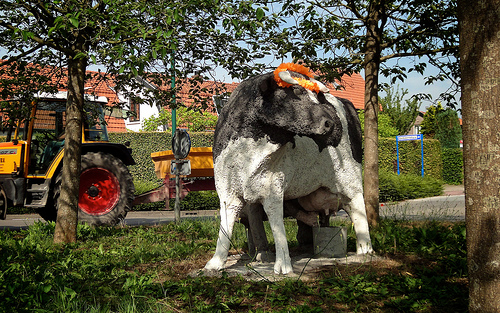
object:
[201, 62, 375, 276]
cow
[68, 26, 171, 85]
tree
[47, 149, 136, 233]
tire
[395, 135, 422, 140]
sign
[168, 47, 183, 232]
pole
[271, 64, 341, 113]
top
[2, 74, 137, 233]
tractor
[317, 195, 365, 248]
udder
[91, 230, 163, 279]
ground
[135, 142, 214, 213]
trailer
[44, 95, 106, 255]
trunk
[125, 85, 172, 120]
roof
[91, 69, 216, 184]
building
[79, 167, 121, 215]
wheel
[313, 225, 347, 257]
bucket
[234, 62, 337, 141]
head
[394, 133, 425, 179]
post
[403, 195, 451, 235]
slab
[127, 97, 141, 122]
window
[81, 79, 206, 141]
side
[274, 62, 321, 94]
lei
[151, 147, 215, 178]
box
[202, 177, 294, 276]
front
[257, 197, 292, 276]
leg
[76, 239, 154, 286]
grass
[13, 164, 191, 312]
park